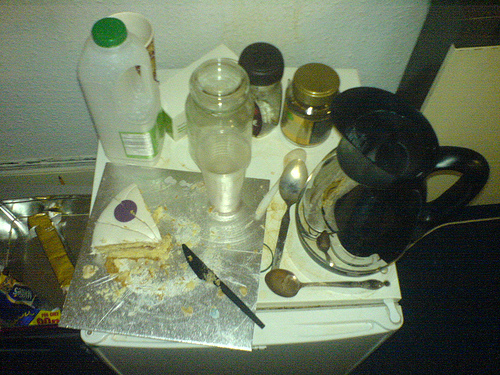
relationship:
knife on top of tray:
[181, 242, 265, 328] [62, 161, 269, 354]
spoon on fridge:
[264, 270, 385, 298] [257, 286, 403, 308]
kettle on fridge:
[297, 87, 490, 277] [257, 286, 403, 308]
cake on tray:
[94, 183, 163, 259] [62, 161, 269, 354]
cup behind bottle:
[112, 12, 156, 49] [76, 15, 164, 169]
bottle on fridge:
[240, 40, 284, 136] [257, 286, 403, 308]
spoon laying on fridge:
[264, 270, 385, 298] [257, 286, 403, 308]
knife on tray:
[181, 242, 265, 328] [62, 161, 269, 354]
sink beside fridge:
[1, 192, 91, 360] [257, 286, 403, 308]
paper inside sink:
[1, 275, 60, 325] [1, 192, 91, 360]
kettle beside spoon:
[297, 87, 490, 277] [272, 158, 309, 274]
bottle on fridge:
[280, 64, 340, 148] [257, 286, 403, 308]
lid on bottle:
[294, 63, 341, 102] [280, 64, 340, 148]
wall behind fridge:
[0, 2, 95, 165] [257, 286, 403, 308]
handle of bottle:
[137, 48, 154, 94] [76, 15, 164, 169]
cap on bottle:
[92, 18, 129, 48] [76, 15, 164, 169]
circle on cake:
[116, 198, 138, 222] [94, 183, 163, 259]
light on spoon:
[291, 163, 301, 180] [272, 158, 309, 274]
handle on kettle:
[416, 141, 488, 240] [297, 87, 490, 277]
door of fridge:
[82, 305, 399, 375] [257, 286, 403, 308]